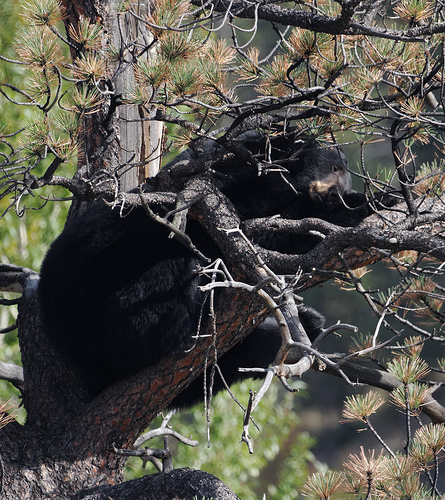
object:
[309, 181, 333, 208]
mouth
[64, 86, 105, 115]
pine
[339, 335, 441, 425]
pine needles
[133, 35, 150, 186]
gap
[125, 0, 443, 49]
branches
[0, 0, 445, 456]
branch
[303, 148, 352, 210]
muzzle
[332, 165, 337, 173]
eye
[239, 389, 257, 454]
seven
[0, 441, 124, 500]
bark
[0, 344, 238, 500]
trunk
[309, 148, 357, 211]
face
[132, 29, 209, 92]
pine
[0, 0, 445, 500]
tree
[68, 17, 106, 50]
pine needles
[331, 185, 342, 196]
nose